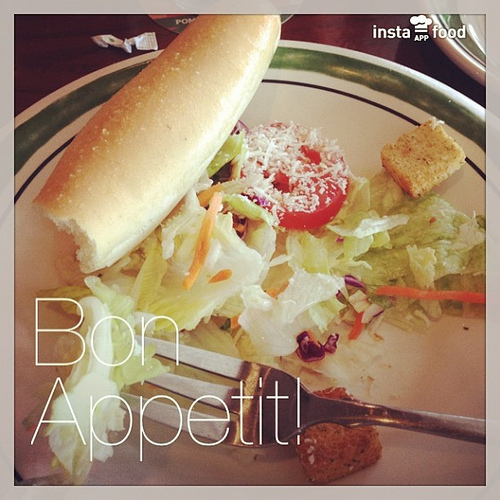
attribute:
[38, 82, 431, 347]
salad — mixed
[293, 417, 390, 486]
crouton — under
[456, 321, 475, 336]
plate — white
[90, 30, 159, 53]
straw wrapper — white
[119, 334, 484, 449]
fork — silver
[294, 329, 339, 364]
cabbage — purple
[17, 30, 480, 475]
plate — white, green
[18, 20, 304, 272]
bread stick — eaten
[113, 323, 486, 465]
fork — silver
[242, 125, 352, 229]
tomato — red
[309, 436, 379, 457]
cake — brown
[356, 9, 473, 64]
logo — white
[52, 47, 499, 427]
plate — white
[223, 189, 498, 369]
vegetable — green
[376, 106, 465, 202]
crouton — brown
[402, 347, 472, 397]
plate — white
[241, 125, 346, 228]
cheese — white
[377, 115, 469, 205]
crouton — brown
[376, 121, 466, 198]
crouton — square, shaped